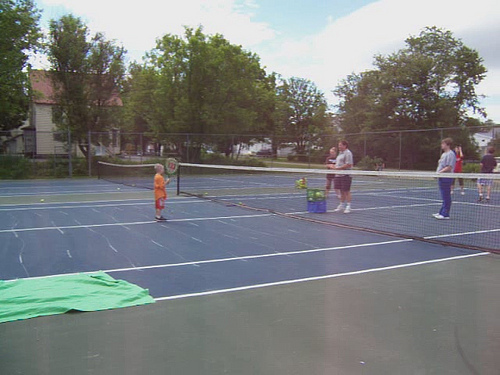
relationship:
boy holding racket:
[154, 163, 170, 220] [160, 147, 190, 185]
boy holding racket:
[154, 163, 170, 220] [150, 136, 187, 190]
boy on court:
[154, 163, 170, 220] [0, 187, 485, 323]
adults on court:
[433, 137, 453, 220] [0, 187, 485, 323]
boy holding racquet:
[154, 163, 170, 220] [160, 153, 180, 178]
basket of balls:
[302, 191, 330, 216] [308, 191, 323, 200]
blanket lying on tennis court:
[0, 270, 154, 322] [2, 170, 497, 332]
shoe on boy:
[153, 213, 168, 223] [149, 159, 174, 224]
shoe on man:
[344, 205, 355, 221] [328, 139, 361, 215]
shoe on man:
[334, 203, 346, 215] [335, 135, 355, 213]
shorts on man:
[327, 175, 357, 196] [328, 132, 355, 214]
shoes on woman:
[431, 210, 451, 221] [432, 137, 457, 219]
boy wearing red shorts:
[155, 164, 170, 222] [153, 194, 165, 209]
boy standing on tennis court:
[154, 163, 170, 220] [2, 174, 499, 374]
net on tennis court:
[175, 160, 499, 247] [17, 181, 466, 277]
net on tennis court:
[178, 163, 500, 255] [7, 158, 487, 340]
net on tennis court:
[81, 149, 164, 194] [7, 158, 487, 340]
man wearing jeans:
[432, 137, 454, 221] [434, 177, 453, 216]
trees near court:
[332, 23, 490, 173] [1, 183, 499, 331]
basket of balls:
[307, 189, 325, 202] [304, 185, 322, 203]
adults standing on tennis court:
[433, 137, 453, 220] [2, 174, 499, 374]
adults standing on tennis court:
[334, 138, 356, 212] [2, 174, 499, 374]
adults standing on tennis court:
[477, 143, 497, 198] [2, 174, 499, 374]